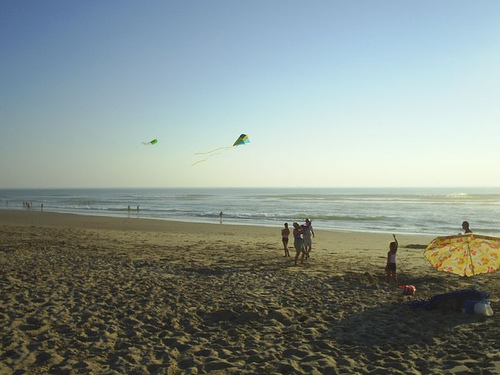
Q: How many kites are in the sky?
A: Two.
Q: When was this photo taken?
A: Outside, during the daytime.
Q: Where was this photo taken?
A: At the beach.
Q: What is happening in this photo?
A: People are flying kites.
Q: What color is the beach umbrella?
A: Yellow.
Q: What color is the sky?
A: Blue.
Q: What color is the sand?
A: Beige.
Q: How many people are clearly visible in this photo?
A: Five.